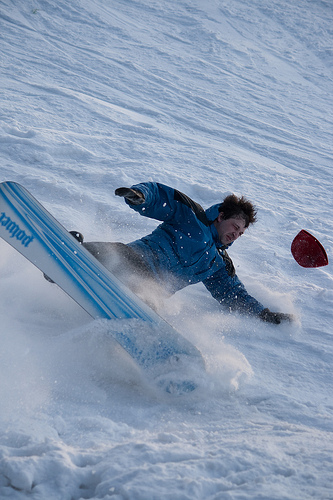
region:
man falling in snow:
[58, 177, 280, 394]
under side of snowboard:
[7, 192, 208, 394]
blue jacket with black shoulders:
[141, 184, 260, 319]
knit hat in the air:
[287, 221, 329, 276]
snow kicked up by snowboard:
[193, 325, 244, 390]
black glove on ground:
[257, 303, 301, 329]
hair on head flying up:
[220, 190, 265, 223]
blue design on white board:
[60, 245, 108, 293]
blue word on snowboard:
[2, 211, 37, 250]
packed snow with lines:
[175, 86, 273, 115]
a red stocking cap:
[286, 221, 330, 278]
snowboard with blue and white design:
[1, 172, 215, 407]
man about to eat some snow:
[0, 150, 309, 402]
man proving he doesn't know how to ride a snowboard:
[0, 167, 296, 403]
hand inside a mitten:
[112, 183, 150, 208]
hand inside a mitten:
[253, 306, 294, 329]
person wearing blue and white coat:
[0, 178, 297, 406]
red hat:
[286, 225, 330, 273]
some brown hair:
[219, 191, 261, 223]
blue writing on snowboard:
[0, 211, 33, 249]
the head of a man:
[206, 190, 261, 250]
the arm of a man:
[198, 260, 266, 317]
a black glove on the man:
[258, 303, 297, 330]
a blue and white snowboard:
[0, 179, 213, 401]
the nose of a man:
[230, 227, 243, 240]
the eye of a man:
[230, 219, 241, 230]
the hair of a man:
[218, 192, 258, 227]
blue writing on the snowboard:
[0, 210, 36, 250]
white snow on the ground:
[0, 0, 332, 499]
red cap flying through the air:
[288, 227, 328, 272]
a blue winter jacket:
[112, 161, 277, 328]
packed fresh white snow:
[15, 394, 309, 498]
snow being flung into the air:
[0, 306, 73, 415]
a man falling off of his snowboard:
[0, 161, 313, 445]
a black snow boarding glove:
[260, 297, 299, 338]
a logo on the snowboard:
[0, 205, 39, 251]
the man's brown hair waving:
[212, 187, 261, 227]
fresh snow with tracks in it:
[42, 9, 300, 156]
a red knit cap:
[280, 210, 328, 278]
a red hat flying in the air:
[282, 217, 331, 283]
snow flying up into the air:
[72, 327, 113, 365]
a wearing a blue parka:
[119, 172, 283, 334]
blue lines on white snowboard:
[30, 210, 79, 287]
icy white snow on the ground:
[211, 426, 295, 469]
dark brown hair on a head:
[232, 195, 248, 214]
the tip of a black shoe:
[74, 231, 83, 240]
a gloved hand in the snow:
[266, 306, 302, 329]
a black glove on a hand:
[115, 183, 144, 204]